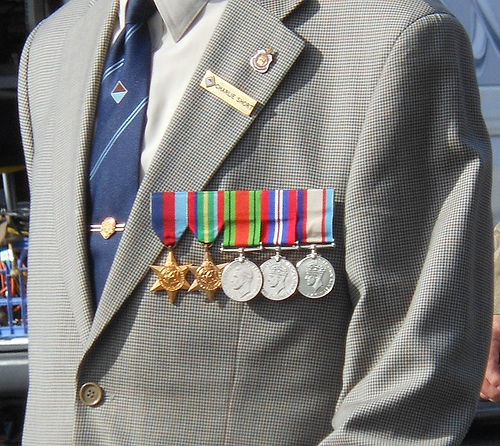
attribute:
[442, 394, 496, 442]
tomato — cut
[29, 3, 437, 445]
jacket — plaid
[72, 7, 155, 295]
tie — blue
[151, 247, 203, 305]
star — gold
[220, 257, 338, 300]
pendant — silver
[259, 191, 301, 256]
ribbon — red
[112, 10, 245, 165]
shirt — white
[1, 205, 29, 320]
blender — red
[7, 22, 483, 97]
shoulders — broad